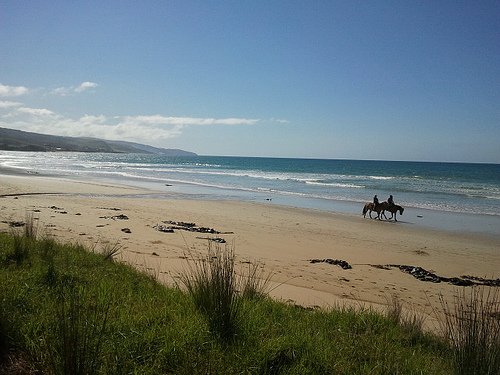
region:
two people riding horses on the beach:
[363, 195, 403, 220]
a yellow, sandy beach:
[0, 164, 499, 355]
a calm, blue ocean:
[0, 148, 499, 233]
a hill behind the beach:
[0, 124, 197, 155]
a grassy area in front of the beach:
[0, 226, 499, 373]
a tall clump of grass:
[173, 231, 292, 339]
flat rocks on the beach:
[34, 205, 499, 288]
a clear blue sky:
[2, 0, 499, 163]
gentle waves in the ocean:
[68, 157, 497, 204]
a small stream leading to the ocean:
[3, 189, 248, 202]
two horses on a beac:
[356, 189, 433, 234]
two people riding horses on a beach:
[366, 183, 406, 233]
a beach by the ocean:
[19, 119, 326, 246]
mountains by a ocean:
[16, 122, 205, 202]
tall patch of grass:
[150, 232, 332, 358]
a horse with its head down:
[373, 194, 418, 222]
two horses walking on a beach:
[327, 170, 421, 242]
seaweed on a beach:
[307, 248, 489, 311]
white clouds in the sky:
[63, 102, 260, 162]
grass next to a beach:
[33, 229, 401, 369]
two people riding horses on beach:
[276, 165, 434, 257]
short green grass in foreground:
[115, 323, 364, 364]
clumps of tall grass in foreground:
[176, 235, 267, 354]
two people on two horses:
[356, 190, 408, 225]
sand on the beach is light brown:
[253, 202, 305, 249]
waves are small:
[176, 157, 362, 217]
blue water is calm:
[258, 150, 475, 185]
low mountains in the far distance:
[1, 115, 201, 168]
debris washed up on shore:
[144, 206, 225, 252]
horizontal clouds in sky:
[16, 70, 242, 156]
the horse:
[355, 172, 427, 280]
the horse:
[336, 161, 441, 364]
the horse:
[343, 188, 400, 262]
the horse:
[328, 186, 407, 301]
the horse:
[312, 193, 427, 218]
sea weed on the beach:
[280, 225, 387, 337]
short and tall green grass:
[69, 278, 147, 347]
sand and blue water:
[277, 177, 339, 215]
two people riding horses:
[355, 190, 409, 246]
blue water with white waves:
[229, 162, 307, 199]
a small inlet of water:
[53, 179, 210, 257]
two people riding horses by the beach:
[353, 180, 410, 283]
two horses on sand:
[323, 204, 405, 287]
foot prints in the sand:
[182, 227, 392, 298]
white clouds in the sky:
[92, 80, 310, 154]